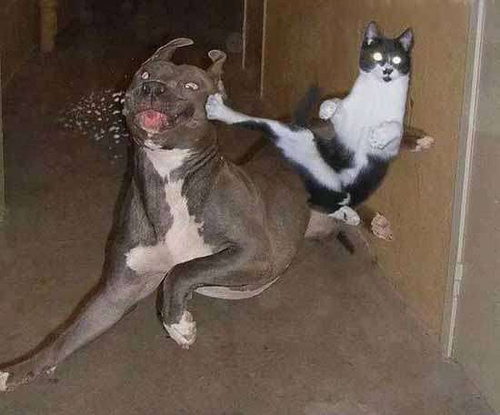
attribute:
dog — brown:
[0, 36, 437, 391]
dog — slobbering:
[24, 41, 361, 367]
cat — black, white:
[207, 22, 412, 213]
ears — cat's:
[360, 21, 424, 47]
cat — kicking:
[321, 60, 406, 230]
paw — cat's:
[331, 192, 365, 235]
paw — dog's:
[166, 307, 207, 353]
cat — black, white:
[202, 20, 437, 225]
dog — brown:
[11, 17, 316, 392]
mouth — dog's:
[124, 103, 194, 146]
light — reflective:
[371, 46, 415, 74]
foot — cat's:
[201, 89, 239, 126]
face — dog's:
[114, 28, 231, 151]